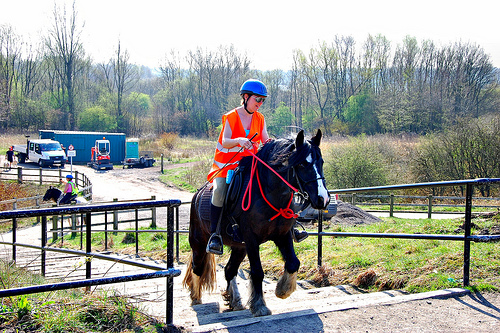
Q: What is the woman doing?
A: Riding a horse up stairs.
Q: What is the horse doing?
A: Walking up a flight of stairs.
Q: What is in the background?
A: Tall trees.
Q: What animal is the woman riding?
A: Horse.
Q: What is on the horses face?
A: Harness.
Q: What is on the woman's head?
A: Helmet.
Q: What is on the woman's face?
A: Glasses.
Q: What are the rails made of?
A: Metal.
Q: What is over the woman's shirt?
A: Safety vest.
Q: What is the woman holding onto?
A: Reins.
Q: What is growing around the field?
A: Trees.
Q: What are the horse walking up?
A: Stairs.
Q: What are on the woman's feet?
A: Boots.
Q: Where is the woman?
A: On a horse.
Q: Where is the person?
A: On a horse.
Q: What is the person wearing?
A: A riding helmet.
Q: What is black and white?
A: A horse.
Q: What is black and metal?
A: A stairway railing.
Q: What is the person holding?
A: Red horse reins.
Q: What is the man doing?
A: Riding horse.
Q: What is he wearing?
A: Helmet.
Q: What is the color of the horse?
A: Black and white.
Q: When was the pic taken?
A: During the day.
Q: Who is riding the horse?
A: The man.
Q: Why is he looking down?
A: So as not to fall.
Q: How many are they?
A: 4.